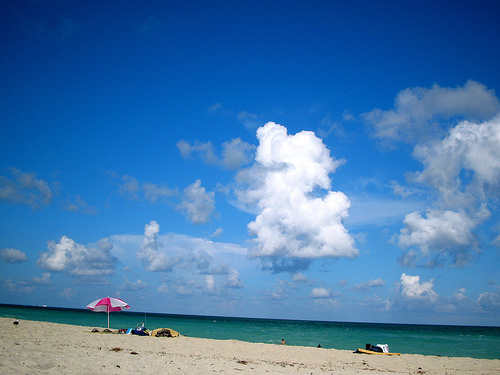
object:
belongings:
[150, 319, 182, 339]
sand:
[11, 320, 236, 348]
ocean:
[8, 306, 492, 361]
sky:
[4, 3, 492, 300]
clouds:
[238, 106, 366, 267]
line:
[3, 301, 499, 330]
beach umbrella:
[85, 294, 130, 327]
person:
[276, 337, 288, 343]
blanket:
[147, 324, 181, 337]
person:
[122, 318, 146, 336]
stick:
[106, 308, 112, 328]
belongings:
[102, 321, 118, 336]